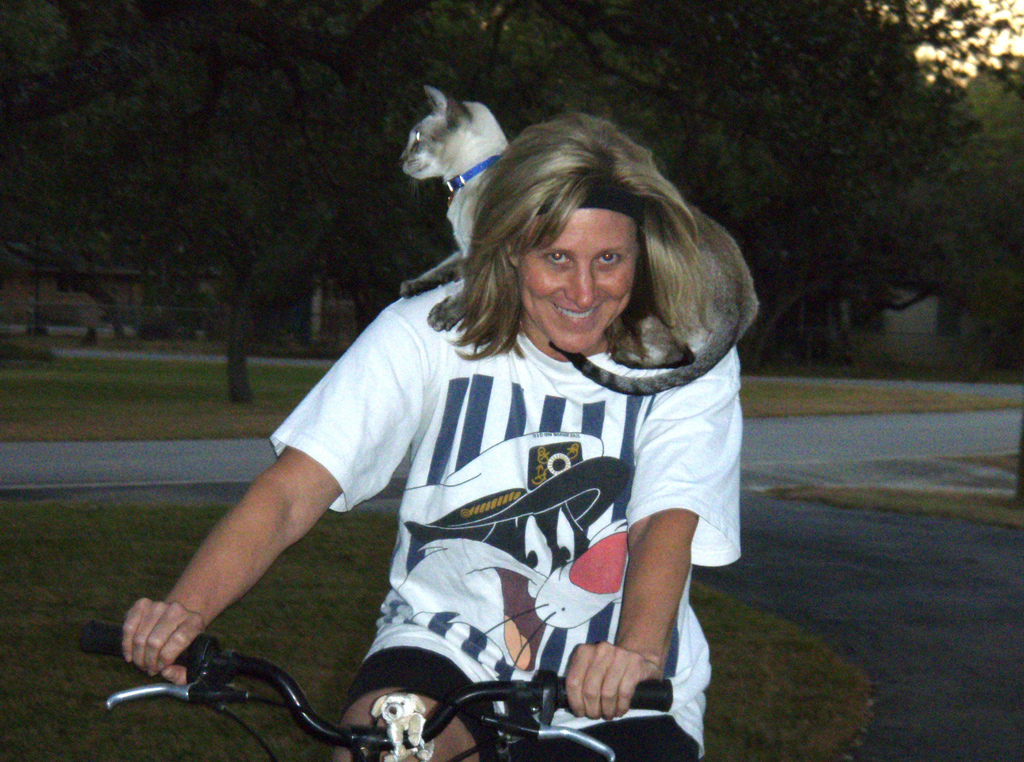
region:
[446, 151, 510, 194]
blue collar on cat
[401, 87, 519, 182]
head on the cat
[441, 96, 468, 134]
ear on the cat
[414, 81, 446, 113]
ear on the cat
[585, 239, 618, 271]
left eye on woman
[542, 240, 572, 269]
right eye on the woman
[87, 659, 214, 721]
silver brake on bike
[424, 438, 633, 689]
character on her shirt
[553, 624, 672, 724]
left hand on woman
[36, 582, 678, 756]
a two wheeled bicycle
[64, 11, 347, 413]
a tree in a field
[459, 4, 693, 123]
a tree in a field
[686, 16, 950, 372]
a tree in a field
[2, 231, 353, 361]
a house on a street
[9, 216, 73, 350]
a tree in a field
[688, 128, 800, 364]
a tree in a field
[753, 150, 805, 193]
green leaves on the tree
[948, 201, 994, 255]
green leaves on the tree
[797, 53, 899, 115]
green leaves on the tree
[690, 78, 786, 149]
green leaves on the tree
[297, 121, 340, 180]
green leaves on the tree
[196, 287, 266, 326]
green leaves on the tree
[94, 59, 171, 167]
green leaves on the tree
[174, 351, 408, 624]
arm on the lady riding a bike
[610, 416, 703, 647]
arm on the lady riding a bike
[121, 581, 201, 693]
hand on the lady riding a bike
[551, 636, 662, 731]
hand on the lady riding a bike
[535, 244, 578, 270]
eye on the lady riding a bike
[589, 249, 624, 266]
eye on the lady riding a bike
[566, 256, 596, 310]
nose on the lady riding a bike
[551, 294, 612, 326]
mouth on the lady riding a bike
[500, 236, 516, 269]
ear on the lady riding a bike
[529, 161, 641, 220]
headband on the lady riding a bike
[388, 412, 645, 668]
cat is on shirt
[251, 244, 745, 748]
woman is wearing a shirt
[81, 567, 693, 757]
woman is riding a bike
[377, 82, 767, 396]
cat is on woman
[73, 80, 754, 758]
Lady on a bike with a cat on her shoulders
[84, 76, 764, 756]
Lady with a cat on her shoulders sits on a bike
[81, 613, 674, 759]
Handle bars on a bike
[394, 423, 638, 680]
Black and white cartoon cat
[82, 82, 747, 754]
Girl with a black headband and a cat on her shoulders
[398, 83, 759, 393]
Cat on a girl's shoulders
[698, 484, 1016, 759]
A winding driveway to the street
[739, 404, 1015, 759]
A turn onto the street for a driveway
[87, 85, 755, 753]
Girl sitting on a bike has a feline around her head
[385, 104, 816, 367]
the hair is blonde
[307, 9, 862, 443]
the cat is on lady shoulder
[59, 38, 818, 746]
lady riding her bike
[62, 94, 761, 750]
lady giving cat a ride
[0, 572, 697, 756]
hands holding handlebars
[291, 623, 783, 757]
the lady is wearing shorts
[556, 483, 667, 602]
the nose is red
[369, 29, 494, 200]
the cat has eye open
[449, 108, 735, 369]
the woman is a blonde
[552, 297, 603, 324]
the woman is smiling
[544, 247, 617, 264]
the woman has red eye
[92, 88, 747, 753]
the woman is riding a bicycle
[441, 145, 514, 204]
the cat has a collar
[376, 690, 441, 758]
a bear figure is on the bicycle